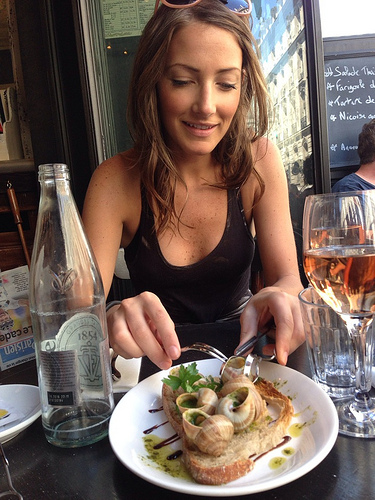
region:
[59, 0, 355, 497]
A woman eating escargot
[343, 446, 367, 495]
A black wooden table surface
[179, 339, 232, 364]
A silver metal fork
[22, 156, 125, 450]
An empty glass bottle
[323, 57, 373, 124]
A chalk board with white chalk writing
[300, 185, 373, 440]
A glass of wine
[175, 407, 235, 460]
A brown snail shell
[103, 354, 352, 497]
Escargot on a white plate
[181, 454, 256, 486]
A piece of crusty bread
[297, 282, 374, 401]
An empty glass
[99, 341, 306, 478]
Escargo on a piece of bread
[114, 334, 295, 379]
silver utensils in her hand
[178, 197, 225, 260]
several freckles on her chest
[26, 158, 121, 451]
a glass bottle with silver label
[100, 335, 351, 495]
a white round plate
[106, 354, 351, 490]
a white plate with food on it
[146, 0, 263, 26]
sunglasses on top of her head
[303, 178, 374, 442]
a large glass of wine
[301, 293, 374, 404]
a short empty glass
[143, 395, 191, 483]
brown lines on the plate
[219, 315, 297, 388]
Woman is holding snail tongs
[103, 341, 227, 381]
Woman is holding a snail fork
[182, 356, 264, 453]
Snails are on toast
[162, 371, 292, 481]
Toast is on a plate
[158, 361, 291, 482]
Toast is on a white plate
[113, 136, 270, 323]
Woman is wearing a shirt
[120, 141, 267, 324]
Woman is wearing a black shirt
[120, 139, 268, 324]
Woman is wearing a tank top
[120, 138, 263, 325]
Woman is wearing a black tank top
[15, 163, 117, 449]
Bottle on the table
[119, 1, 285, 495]
Woman black tank top lunch.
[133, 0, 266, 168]
Long brown hair sunglasses propped head.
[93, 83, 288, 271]
Light skinned freckled body.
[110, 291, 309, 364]
Both hands hold utensils necessary.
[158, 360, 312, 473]
Escargot atop toasted bread.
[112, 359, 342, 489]
White plate garnished sauces.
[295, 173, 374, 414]
Wine glass full amber liquid.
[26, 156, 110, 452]
Empty glass bottle label 1854.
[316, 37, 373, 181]
Menu specials white black chalkboard.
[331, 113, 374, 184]
Dark haired person front blackboard.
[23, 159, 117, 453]
tall clear bottle with silver and black label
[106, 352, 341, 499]
round white ceramic plate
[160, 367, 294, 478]
tan and brown shells on toast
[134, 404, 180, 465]
drizzled chocolate sauce on white plate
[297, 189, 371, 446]
tall wine glass with peach covered beverage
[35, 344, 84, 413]
silver and black label on clear bottle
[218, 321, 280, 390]
silver shell opener with black handle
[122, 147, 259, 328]
black tank top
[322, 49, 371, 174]
black chalk board with white writing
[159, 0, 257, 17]
bottom of a pair of light red framed sunglasses